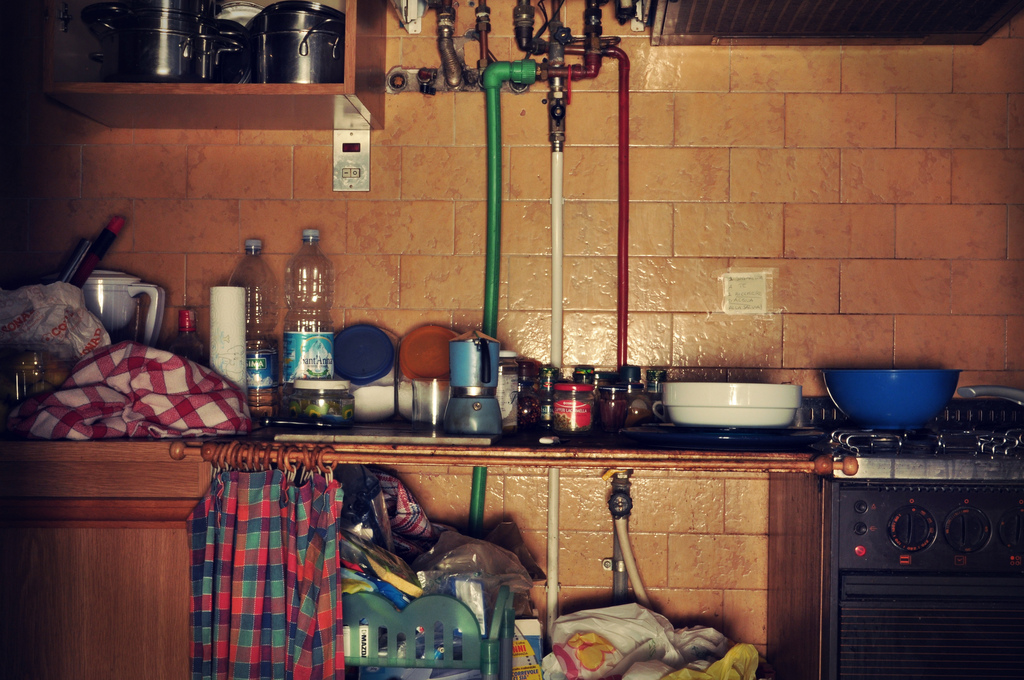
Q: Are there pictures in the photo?
A: No, there are no pictures.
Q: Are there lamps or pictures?
A: No, there are no pictures or lamps.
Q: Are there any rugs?
A: No, there are no rugs.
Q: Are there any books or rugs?
A: No, there are no rugs or books.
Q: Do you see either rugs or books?
A: No, there are no rugs or books.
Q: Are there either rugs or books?
A: No, there are no rugs or books.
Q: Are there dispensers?
A: No, there are no dispensers.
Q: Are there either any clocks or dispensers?
A: No, there are no dispensers or clocks.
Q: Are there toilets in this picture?
A: No, there are no toilets.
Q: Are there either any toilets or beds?
A: No, there are no toilets or beds.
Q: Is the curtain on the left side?
A: Yes, the curtain is on the left of the image.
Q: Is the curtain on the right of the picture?
A: No, the curtain is on the left of the image.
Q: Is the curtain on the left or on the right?
A: The curtain is on the left of the image.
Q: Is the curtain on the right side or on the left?
A: The curtain is on the left of the image.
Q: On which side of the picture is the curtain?
A: The curtain is on the left of the image.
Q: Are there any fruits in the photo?
A: No, there are no fruits.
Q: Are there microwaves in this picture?
A: No, there are no microwaves.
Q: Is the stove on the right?
A: Yes, the stove is on the right of the image.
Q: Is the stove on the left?
A: No, the stove is on the right of the image.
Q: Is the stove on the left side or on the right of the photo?
A: The stove is on the right of the image.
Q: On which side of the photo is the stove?
A: The stove is on the right of the image.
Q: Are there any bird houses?
A: No, there are no bird houses.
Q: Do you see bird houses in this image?
A: No, there are no bird houses.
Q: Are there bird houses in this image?
A: No, there are no bird houses.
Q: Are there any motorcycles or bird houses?
A: No, there are no bird houses or motorcycles.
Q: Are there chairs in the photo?
A: No, there are no chairs.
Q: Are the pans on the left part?
A: Yes, the pans are on the left of the image.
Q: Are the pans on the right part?
A: No, the pans are on the left of the image.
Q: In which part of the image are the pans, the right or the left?
A: The pans are on the left of the image.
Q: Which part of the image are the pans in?
A: The pans are on the left of the image.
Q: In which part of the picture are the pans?
A: The pans are on the left of the image.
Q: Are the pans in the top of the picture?
A: Yes, the pans are in the top of the image.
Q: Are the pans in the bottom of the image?
A: No, the pans are in the top of the image.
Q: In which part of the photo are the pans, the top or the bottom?
A: The pans are in the top of the image.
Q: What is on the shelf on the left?
A: The pans are on the shelf.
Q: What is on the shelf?
A: The pans are on the shelf.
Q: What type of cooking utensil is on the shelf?
A: The cooking utensils are pans.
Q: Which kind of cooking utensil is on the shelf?
A: The cooking utensils are pans.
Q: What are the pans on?
A: The pans are on the shelf.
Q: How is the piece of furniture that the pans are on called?
A: The piece of furniture is a shelf.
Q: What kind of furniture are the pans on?
A: The pans are on the shelf.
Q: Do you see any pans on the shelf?
A: Yes, there are pans on the shelf.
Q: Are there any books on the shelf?
A: No, there are pans on the shelf.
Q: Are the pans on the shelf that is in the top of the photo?
A: Yes, the pans are on the shelf.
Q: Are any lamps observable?
A: No, there are no lamps.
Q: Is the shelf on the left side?
A: Yes, the shelf is on the left of the image.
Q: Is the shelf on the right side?
A: No, the shelf is on the left of the image.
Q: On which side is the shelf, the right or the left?
A: The shelf is on the left of the image.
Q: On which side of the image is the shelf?
A: The shelf is on the left of the image.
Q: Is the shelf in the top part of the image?
A: Yes, the shelf is in the top of the image.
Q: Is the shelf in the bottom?
A: No, the shelf is in the top of the image.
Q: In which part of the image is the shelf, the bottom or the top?
A: The shelf is in the top of the image.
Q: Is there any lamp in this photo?
A: No, there are no lamps.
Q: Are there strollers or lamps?
A: No, there are no lamps or strollers.